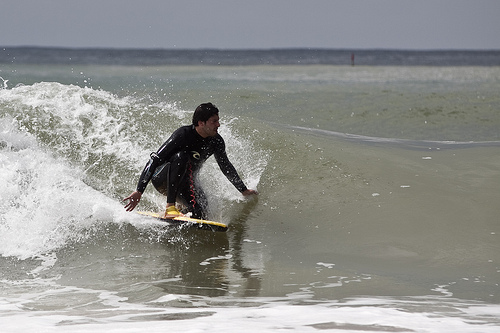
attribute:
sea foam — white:
[33, 87, 127, 249]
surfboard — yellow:
[136, 209, 228, 232]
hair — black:
[191, 100, 218, 125]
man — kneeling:
[120, 100, 261, 217]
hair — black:
[191, 101, 213, 123]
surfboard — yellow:
[160, 198, 240, 240]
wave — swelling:
[0, 72, 496, 299]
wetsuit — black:
[143, 119, 255, 225]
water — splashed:
[1, 85, 227, 252]